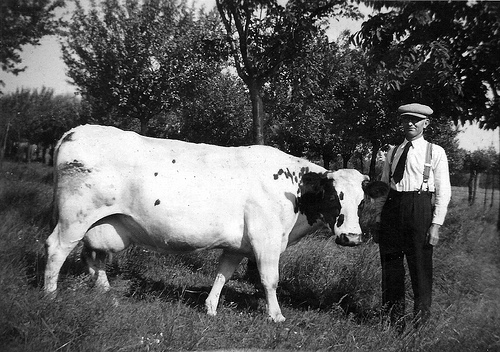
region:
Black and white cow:
[41, 121, 391, 326]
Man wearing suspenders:
[377, 100, 452, 335]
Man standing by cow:
[42, 100, 454, 328]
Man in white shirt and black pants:
[375, 102, 454, 330]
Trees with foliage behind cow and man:
[41, 40, 496, 317]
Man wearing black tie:
[371, 100, 448, 320]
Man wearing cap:
[375, 100, 451, 325]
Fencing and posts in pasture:
[450, 185, 495, 210]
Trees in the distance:
[0, 81, 82, 163]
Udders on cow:
[85, 215, 135, 265]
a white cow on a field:
[33, 111, 395, 335]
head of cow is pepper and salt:
[297, 163, 394, 261]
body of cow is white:
[39, 119, 378, 336]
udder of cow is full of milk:
[81, 216, 138, 256]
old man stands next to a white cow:
[364, 94, 456, 333]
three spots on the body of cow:
[137, 151, 187, 216]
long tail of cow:
[36, 121, 72, 235]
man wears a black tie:
[369, 88, 457, 331]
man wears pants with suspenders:
[368, 97, 459, 328]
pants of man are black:
[370, 188, 443, 333]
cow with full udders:
[41, 122, 390, 326]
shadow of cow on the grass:
[18, 243, 378, 325]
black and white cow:
[39, 119, 391, 326]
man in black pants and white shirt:
[367, 100, 452, 322]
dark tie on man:
[388, 136, 413, 181]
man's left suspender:
[420, 140, 435, 191]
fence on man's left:
[450, 167, 496, 203]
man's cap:
[398, 102, 433, 117]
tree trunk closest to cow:
[245, 90, 270, 145]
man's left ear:
[420, 118, 431, 129]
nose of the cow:
[334, 220, 371, 268]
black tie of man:
[382, 141, 421, 181]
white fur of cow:
[125, 141, 252, 224]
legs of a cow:
[17, 215, 154, 335]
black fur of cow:
[290, 159, 345, 220]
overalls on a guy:
[412, 135, 442, 196]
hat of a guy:
[373, 75, 454, 120]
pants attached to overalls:
[370, 185, 480, 326]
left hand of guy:
[418, 213, 455, 254]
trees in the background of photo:
[116, 23, 393, 124]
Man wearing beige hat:
[386, 98, 441, 119]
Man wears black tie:
[389, 143, 414, 185]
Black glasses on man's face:
[396, 113, 423, 128]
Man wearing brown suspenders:
[420, 136, 437, 191]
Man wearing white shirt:
[410, 151, 420, 183]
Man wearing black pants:
[379, 193, 428, 294]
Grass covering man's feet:
[371, 293, 437, 333]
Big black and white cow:
[36, 108, 377, 338]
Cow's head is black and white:
[285, 156, 395, 264]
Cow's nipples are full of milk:
[75, 241, 127, 271]